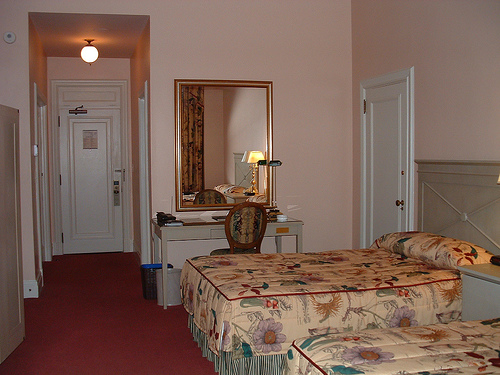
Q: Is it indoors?
A: Yes, it is indoors.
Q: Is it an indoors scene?
A: Yes, it is indoors.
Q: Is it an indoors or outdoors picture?
A: It is indoors.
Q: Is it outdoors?
A: No, it is indoors.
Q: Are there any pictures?
A: No, there are no pictures.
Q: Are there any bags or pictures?
A: No, there are no pictures or bags.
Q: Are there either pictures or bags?
A: No, there are no pictures or bags.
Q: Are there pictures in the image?
A: No, there are no pictures.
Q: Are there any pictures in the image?
A: No, there are no pictures.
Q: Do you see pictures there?
A: No, there are no pictures.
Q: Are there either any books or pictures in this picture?
A: No, there are no pictures or books.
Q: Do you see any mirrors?
A: Yes, there is a mirror.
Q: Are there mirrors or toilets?
A: Yes, there is a mirror.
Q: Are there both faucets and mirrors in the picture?
A: No, there is a mirror but no faucets.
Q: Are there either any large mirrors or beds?
A: Yes, there is a large mirror.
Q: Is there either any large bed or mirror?
A: Yes, there is a large mirror.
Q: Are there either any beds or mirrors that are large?
A: Yes, the mirror is large.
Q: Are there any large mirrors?
A: Yes, there is a large mirror.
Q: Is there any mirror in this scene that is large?
A: Yes, there is a mirror that is large.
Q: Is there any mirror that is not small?
A: Yes, there is a large mirror.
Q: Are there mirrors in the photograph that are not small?
A: Yes, there is a large mirror.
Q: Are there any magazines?
A: No, there are no magazines.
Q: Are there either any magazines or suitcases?
A: No, there are no magazines or suitcases.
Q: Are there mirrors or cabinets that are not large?
A: No, there is a mirror but it is large.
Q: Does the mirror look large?
A: Yes, the mirror is large.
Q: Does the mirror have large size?
A: Yes, the mirror is large.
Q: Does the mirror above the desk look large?
A: Yes, the mirror is large.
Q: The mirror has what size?
A: The mirror is large.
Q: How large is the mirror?
A: The mirror is large.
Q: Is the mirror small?
A: No, the mirror is large.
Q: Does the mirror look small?
A: No, the mirror is large.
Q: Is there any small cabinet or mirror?
A: No, there is a mirror but it is large.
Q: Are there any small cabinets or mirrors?
A: No, there is a mirror but it is large.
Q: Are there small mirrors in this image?
A: No, there is a mirror but it is large.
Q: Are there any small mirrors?
A: No, there is a mirror but it is large.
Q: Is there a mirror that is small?
A: No, there is a mirror but it is large.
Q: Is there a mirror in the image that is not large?
A: No, there is a mirror but it is large.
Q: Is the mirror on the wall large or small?
A: The mirror is large.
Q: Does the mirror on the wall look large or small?
A: The mirror is large.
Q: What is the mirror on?
A: The mirror is on the wall.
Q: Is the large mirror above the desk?
A: Yes, the mirror is above the desk.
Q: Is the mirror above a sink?
A: No, the mirror is above the desk.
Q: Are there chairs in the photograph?
A: Yes, there is a chair.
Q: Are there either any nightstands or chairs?
A: Yes, there is a chair.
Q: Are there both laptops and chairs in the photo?
A: No, there is a chair but no laptops.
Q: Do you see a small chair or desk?
A: Yes, there is a small chair.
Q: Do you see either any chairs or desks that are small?
A: Yes, the chair is small.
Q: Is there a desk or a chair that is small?
A: Yes, the chair is small.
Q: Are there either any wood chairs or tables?
A: Yes, there is a wood chair.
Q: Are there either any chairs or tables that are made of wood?
A: Yes, the chair is made of wood.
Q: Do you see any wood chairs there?
A: Yes, there is a wood chair.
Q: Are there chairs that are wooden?
A: Yes, there is a chair that is wooden.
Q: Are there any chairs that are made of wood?
A: Yes, there is a chair that is made of wood.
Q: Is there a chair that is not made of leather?
A: Yes, there is a chair that is made of wood.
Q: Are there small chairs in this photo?
A: Yes, there is a small chair.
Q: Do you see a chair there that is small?
A: Yes, there is a chair that is small.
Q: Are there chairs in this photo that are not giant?
A: Yes, there is a small chair.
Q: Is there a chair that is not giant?
A: Yes, there is a small chair.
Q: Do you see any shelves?
A: No, there are no shelves.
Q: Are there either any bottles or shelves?
A: No, there are no shelves or bottles.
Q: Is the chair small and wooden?
A: Yes, the chair is small and wooden.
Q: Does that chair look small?
A: Yes, the chair is small.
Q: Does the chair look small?
A: Yes, the chair is small.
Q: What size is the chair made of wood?
A: The chair is small.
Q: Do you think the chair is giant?
A: No, the chair is small.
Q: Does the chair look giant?
A: No, the chair is small.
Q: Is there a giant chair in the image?
A: No, there is a chair but it is small.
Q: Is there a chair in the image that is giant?
A: No, there is a chair but it is small.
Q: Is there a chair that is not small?
A: No, there is a chair but it is small.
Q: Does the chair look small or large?
A: The chair is small.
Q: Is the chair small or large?
A: The chair is small.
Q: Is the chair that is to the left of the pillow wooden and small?
A: Yes, the chair is wooden and small.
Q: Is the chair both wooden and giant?
A: No, the chair is wooden but small.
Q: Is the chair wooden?
A: Yes, the chair is wooden.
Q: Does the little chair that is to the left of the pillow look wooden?
A: Yes, the chair is wooden.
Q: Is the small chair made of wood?
A: Yes, the chair is made of wood.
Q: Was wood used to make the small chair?
A: Yes, the chair is made of wood.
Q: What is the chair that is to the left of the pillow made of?
A: The chair is made of wood.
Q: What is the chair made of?
A: The chair is made of wood.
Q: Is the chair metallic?
A: No, the chair is wooden.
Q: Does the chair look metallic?
A: No, the chair is wooden.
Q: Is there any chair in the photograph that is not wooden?
A: No, there is a chair but it is wooden.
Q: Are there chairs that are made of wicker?
A: No, there is a chair but it is made of wood.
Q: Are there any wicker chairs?
A: No, there is a chair but it is made of wood.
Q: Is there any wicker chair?
A: No, there is a chair but it is made of wood.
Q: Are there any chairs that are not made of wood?
A: No, there is a chair but it is made of wood.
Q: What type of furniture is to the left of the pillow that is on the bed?
A: The piece of furniture is a chair.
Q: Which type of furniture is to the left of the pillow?
A: The piece of furniture is a chair.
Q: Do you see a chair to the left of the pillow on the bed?
A: Yes, there is a chair to the left of the pillow.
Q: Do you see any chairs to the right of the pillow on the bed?
A: No, the chair is to the left of the pillow.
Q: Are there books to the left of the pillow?
A: No, there is a chair to the left of the pillow.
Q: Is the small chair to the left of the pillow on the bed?
A: Yes, the chair is to the left of the pillow.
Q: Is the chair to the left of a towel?
A: No, the chair is to the left of the pillow.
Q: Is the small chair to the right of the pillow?
A: No, the chair is to the left of the pillow.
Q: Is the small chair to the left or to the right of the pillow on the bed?
A: The chair is to the left of the pillow.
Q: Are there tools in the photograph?
A: No, there are no tools.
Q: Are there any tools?
A: No, there are no tools.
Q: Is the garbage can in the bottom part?
A: Yes, the garbage can is in the bottom of the image.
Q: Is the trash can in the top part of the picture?
A: No, the trash can is in the bottom of the image.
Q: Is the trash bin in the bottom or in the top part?
A: The trash bin is in the bottom of the image.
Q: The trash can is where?
A: The trash can is on the floor.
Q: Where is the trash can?
A: The trash can is on the floor.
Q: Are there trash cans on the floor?
A: Yes, there is a trash can on the floor.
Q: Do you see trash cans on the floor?
A: Yes, there is a trash can on the floor.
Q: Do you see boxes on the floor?
A: No, there is a trash can on the floor.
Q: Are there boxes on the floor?
A: No, there is a trash can on the floor.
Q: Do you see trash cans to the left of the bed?
A: Yes, there is a trash can to the left of the bed.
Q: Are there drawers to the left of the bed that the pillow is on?
A: No, there is a trash can to the left of the bed.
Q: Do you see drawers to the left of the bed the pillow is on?
A: No, there is a trash can to the left of the bed.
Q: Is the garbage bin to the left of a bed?
A: Yes, the garbage bin is to the left of a bed.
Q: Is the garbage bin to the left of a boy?
A: No, the garbage bin is to the left of a bed.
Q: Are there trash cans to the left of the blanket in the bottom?
A: Yes, there is a trash can to the left of the blanket.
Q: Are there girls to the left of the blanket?
A: No, there is a trash can to the left of the blanket.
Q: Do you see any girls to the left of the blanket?
A: No, there is a trash can to the left of the blanket.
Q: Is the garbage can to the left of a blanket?
A: Yes, the garbage can is to the left of a blanket.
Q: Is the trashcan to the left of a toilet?
A: No, the trashcan is to the left of a blanket.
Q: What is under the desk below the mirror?
A: The trash bin is under the desk.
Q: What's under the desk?
A: The trash bin is under the desk.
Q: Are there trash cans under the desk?
A: Yes, there is a trash can under the desk.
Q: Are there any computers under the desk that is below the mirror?
A: No, there is a trash can under the desk.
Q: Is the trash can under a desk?
A: Yes, the trash can is under a desk.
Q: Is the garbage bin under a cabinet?
A: No, the garbage bin is under a desk.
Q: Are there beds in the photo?
A: Yes, there is a bed.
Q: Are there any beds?
A: Yes, there is a bed.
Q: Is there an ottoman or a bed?
A: Yes, there is a bed.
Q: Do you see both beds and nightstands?
A: Yes, there are both a bed and a nightstand.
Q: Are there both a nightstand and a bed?
A: Yes, there are both a bed and a nightstand.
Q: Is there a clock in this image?
A: No, there are no clocks.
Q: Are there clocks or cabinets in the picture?
A: No, there are no clocks or cabinets.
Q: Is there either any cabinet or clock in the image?
A: No, there are no clocks or cabinets.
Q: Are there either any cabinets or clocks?
A: No, there are no clocks or cabinets.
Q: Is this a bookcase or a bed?
A: This is a bed.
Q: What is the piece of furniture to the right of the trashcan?
A: The piece of furniture is a bed.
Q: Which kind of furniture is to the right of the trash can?
A: The piece of furniture is a bed.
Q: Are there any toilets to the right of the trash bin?
A: No, there is a bed to the right of the trash bin.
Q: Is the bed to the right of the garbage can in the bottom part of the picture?
A: Yes, the bed is to the right of the garbage can.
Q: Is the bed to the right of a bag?
A: No, the bed is to the right of the garbage can.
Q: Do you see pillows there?
A: Yes, there is a pillow.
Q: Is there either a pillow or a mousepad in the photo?
A: Yes, there is a pillow.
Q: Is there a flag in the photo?
A: No, there are no flags.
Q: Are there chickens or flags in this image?
A: No, there are no flags or chickens.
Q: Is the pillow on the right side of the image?
A: Yes, the pillow is on the right of the image.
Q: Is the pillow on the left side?
A: No, the pillow is on the right of the image.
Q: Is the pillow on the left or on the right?
A: The pillow is on the right of the image.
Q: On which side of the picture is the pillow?
A: The pillow is on the right of the image.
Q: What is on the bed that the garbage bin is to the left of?
A: The pillow is on the bed.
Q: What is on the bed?
A: The pillow is on the bed.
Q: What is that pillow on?
A: The pillow is on the bed.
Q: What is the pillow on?
A: The pillow is on the bed.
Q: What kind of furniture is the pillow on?
A: The pillow is on the bed.